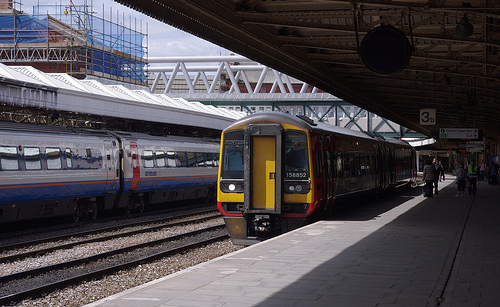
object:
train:
[213, 127, 417, 204]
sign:
[416, 105, 438, 128]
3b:
[420, 111, 435, 127]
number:
[281, 168, 313, 183]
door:
[244, 133, 279, 215]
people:
[418, 152, 500, 204]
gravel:
[6, 220, 237, 307]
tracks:
[2, 198, 230, 304]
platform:
[86, 180, 496, 305]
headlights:
[223, 183, 241, 192]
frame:
[244, 121, 284, 217]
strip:
[0, 171, 217, 188]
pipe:
[120, 51, 251, 65]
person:
[454, 160, 469, 194]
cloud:
[18, 1, 126, 19]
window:
[140, 152, 158, 170]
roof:
[1, 61, 246, 132]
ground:
[2, 173, 492, 303]